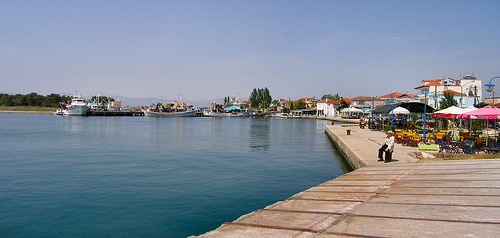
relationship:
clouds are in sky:
[146, 60, 240, 101] [8, 4, 496, 112]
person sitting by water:
[378, 130, 395, 163] [273, 124, 345, 177]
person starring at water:
[378, 130, 395, 163] [80, 137, 209, 188]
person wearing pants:
[372, 124, 416, 174] [375, 139, 391, 163]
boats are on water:
[42, 90, 249, 127] [5, 114, 272, 200]